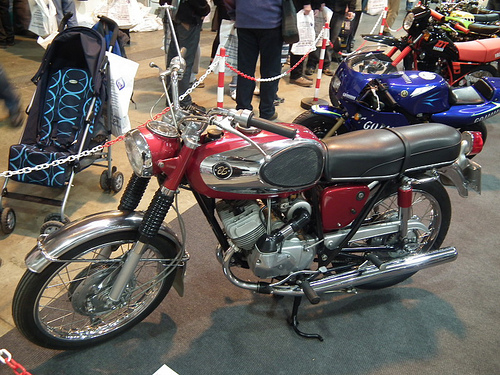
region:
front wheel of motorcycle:
[14, 205, 174, 350]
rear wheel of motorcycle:
[352, 173, 456, 287]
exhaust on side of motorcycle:
[260, 245, 498, 297]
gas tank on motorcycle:
[191, 120, 326, 205]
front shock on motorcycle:
[100, 128, 205, 315]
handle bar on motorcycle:
[206, 102, 308, 163]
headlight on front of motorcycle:
[119, 126, 156, 183]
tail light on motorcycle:
[463, 128, 485, 158]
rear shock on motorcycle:
[391, 184, 417, 251]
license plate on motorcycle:
[457, 155, 484, 205]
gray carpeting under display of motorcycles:
[15, 5, 496, 366]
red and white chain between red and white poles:
[5, 12, 395, 177]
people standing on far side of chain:
[141, 5, 398, 80]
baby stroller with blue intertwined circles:
[1, 12, 121, 227]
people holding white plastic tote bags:
[205, 1, 335, 71]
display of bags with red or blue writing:
[20, 0, 145, 30]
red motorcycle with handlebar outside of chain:
[10, 60, 470, 340]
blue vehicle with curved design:
[325, 45, 460, 120]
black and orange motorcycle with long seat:
[357, 5, 492, 70]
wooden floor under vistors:
[2, 2, 419, 319]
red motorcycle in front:
[16, 48, 481, 353]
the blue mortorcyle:
[292, 45, 498, 143]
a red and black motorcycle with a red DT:
[367, 7, 499, 84]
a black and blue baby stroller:
[6, 27, 123, 236]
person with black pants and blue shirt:
[235, 0, 280, 120]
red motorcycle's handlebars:
[166, 48, 296, 136]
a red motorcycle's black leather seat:
[326, 121, 463, 177]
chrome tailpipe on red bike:
[300, 247, 457, 289]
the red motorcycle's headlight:
[125, 133, 150, 178]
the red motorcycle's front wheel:
[10, 213, 181, 353]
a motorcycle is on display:
[89, 89, 447, 314]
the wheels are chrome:
[58, 275, 194, 366]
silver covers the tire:
[9, 225, 239, 281]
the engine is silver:
[237, 212, 340, 309]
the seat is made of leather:
[309, 99, 471, 186]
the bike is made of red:
[124, 115, 478, 260]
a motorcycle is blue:
[329, 39, 461, 98]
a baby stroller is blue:
[36, 23, 276, 272]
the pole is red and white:
[172, 56, 292, 102]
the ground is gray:
[186, 303, 280, 359]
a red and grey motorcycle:
[11, 47, 484, 350]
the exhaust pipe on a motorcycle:
[309, 242, 463, 303]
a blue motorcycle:
[295, 50, 497, 150]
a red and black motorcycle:
[371, 10, 499, 83]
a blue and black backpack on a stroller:
[93, 18, 130, 56]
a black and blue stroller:
[0, 11, 126, 238]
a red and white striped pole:
[301, 19, 335, 112]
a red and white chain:
[218, 18, 332, 82]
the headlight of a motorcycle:
[398, 8, 419, 33]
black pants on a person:
[228, 26, 283, 116]